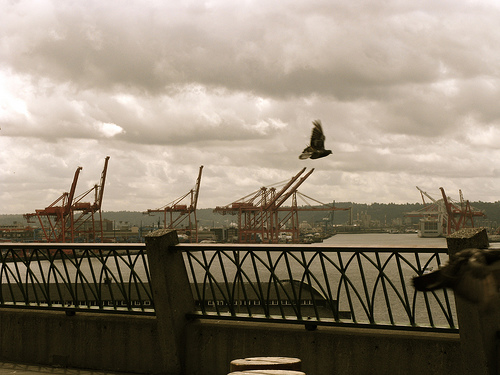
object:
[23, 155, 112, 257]
crane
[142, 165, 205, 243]
crane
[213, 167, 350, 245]
crane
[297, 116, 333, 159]
bird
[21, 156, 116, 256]
equipment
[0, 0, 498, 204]
sky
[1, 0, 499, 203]
clouds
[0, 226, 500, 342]
water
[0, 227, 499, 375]
bridge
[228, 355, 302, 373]
cylinders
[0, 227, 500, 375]
railing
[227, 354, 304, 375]
table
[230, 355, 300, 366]
top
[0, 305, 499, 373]
wall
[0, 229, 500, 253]
handle bars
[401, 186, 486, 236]
crane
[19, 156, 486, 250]
machines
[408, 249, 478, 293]
face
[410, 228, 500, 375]
black dog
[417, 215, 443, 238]
boat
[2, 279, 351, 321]
dock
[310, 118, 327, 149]
wings